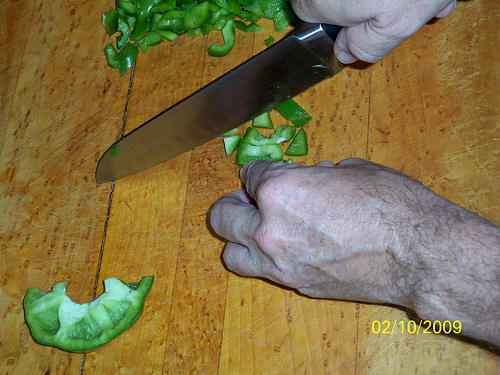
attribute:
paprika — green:
[101, 2, 289, 75]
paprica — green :
[211, 132, 313, 195]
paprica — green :
[39, 260, 208, 370]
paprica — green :
[100, 18, 184, 86]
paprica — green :
[268, 89, 342, 151]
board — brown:
[15, 18, 474, 373]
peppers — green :
[243, 111, 360, 211]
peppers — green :
[105, 34, 152, 105]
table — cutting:
[1, 145, 484, 335]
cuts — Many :
[103, 5, 260, 41]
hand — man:
[175, 159, 438, 309]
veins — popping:
[301, 221, 392, 294]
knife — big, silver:
[66, 29, 351, 191]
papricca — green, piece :
[103, 47, 156, 77]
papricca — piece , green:
[208, 17, 244, 59]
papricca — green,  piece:
[112, 19, 140, 47]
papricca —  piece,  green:
[261, 6, 285, 33]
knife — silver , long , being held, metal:
[95, 28, 347, 188]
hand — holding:
[209, 156, 433, 310]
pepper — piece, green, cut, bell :
[16, 269, 162, 345]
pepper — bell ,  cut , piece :
[292, 129, 318, 171]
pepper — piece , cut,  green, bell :
[213, 20, 253, 51]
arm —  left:
[430, 202, 485, 330]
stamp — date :
[370, 315, 475, 340]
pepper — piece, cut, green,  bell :
[260, 38, 279, 45]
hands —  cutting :
[208, 3, 475, 320]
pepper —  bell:
[221, 117, 311, 159]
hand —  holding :
[211, 162, 406, 298]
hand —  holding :
[287, 0, 437, 54]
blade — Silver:
[92, 91, 283, 189]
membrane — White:
[55, 275, 125, 317]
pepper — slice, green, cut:
[24, 274, 148, 352]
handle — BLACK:
[331, 21, 348, 29]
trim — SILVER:
[308, 32, 327, 55]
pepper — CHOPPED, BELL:
[112, 1, 192, 46]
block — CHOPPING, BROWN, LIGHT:
[202, 322, 274, 365]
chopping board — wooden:
[2, 2, 483, 372]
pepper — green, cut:
[219, 96, 312, 169]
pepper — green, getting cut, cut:
[20, 273, 157, 354]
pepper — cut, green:
[115, 42, 137, 77]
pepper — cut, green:
[113, 12, 131, 49]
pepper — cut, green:
[160, 9, 191, 20]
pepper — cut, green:
[207, 17, 237, 57]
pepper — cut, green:
[182, 0, 210, 28]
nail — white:
[337, 48, 357, 66]